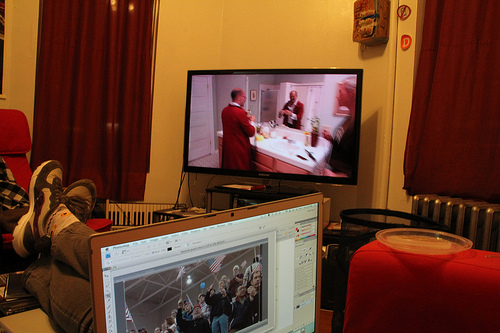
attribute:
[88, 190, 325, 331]
laptop — used for editing, on, used, being used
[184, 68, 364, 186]
television — playing a show, on, large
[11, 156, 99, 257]
feet — resting, crossed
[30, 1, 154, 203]
curtains — red, dark red, covering the window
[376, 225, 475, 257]
plate — empty, clear, plastic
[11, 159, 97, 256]
sneakers — worn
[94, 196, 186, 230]
keyboard — electric, upside down, black, white, musical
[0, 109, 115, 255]
chair — red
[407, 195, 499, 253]
radiator — silver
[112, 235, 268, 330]
people — in a gym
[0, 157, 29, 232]
fabric — black, white